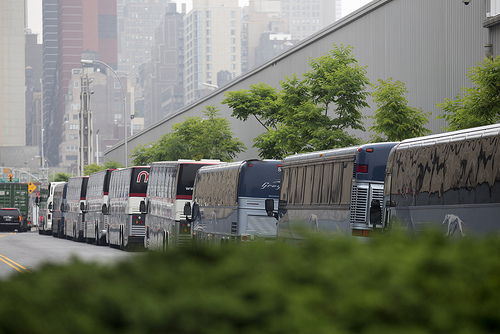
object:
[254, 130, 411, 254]
bus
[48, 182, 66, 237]
bus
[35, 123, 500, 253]
bus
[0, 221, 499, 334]
green bushes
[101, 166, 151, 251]
bus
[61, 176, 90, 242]
bus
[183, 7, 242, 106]
building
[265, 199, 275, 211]
mirror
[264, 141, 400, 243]
bus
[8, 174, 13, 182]
traffic light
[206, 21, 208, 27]
window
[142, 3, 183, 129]
building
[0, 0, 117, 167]
building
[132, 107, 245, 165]
tree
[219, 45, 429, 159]
green trees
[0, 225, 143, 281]
road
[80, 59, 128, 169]
street light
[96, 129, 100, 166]
street light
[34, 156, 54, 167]
street light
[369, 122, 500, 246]
bus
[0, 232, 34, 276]
line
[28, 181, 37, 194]
sign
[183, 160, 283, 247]
bus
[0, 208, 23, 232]
car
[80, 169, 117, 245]
bus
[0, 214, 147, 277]
street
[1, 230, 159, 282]
ground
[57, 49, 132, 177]
building